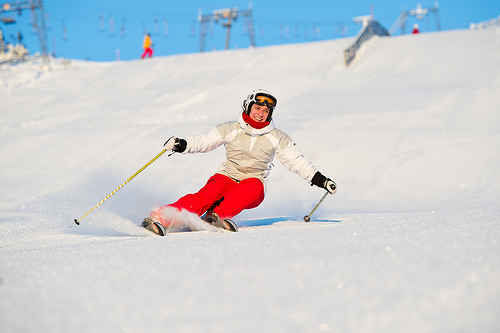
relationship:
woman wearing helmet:
[141, 91, 337, 237] [242, 92, 277, 123]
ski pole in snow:
[70, 149, 169, 225] [0, 30, 499, 332]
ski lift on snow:
[1, 1, 444, 36] [0, 30, 499, 332]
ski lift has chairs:
[1, 1, 444, 36] [3, 16, 19, 24]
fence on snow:
[342, 21, 391, 64] [0, 30, 499, 332]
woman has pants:
[141, 91, 337, 237] [153, 173, 264, 223]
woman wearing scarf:
[141, 91, 337, 237] [239, 112, 270, 129]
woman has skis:
[141, 91, 337, 237] [140, 217, 239, 234]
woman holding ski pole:
[141, 91, 337, 237] [70, 149, 169, 225]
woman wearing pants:
[141, 91, 337, 237] [153, 173, 264, 223]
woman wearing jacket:
[141, 91, 337, 237] [183, 117, 319, 181]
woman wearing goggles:
[141, 91, 337, 237] [254, 94, 277, 108]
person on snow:
[142, 33, 155, 59] [0, 30, 499, 332]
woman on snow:
[141, 91, 337, 237] [0, 30, 499, 332]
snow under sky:
[0, 30, 499, 332] [0, 0, 499, 62]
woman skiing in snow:
[141, 91, 337, 237] [0, 30, 499, 332]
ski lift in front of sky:
[1, 1, 444, 36] [0, 0, 499, 62]